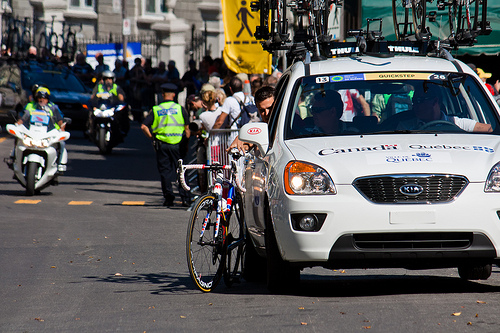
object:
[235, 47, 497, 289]
car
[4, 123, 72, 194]
motorcycle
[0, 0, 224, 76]
building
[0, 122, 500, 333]
road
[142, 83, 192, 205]
man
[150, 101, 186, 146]
fluorescent yellow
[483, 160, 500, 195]
headlight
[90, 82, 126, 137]
cop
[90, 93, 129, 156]
motorcycle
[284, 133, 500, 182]
hood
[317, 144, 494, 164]
words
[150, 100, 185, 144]
vest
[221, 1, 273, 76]
banner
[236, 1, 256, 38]
man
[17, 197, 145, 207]
stripe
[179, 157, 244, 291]
bike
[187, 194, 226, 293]
tire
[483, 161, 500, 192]
light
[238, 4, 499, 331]
right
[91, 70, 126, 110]
policeman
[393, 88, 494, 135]
people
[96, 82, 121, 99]
green vest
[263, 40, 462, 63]
support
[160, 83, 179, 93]
cap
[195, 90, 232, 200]
people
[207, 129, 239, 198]
gate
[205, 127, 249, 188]
fence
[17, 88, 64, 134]
motorcyclists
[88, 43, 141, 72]
sign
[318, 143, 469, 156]
letters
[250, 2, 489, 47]
roof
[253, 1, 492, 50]
bikes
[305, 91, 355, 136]
man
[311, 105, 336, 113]
glasses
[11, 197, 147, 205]
lines